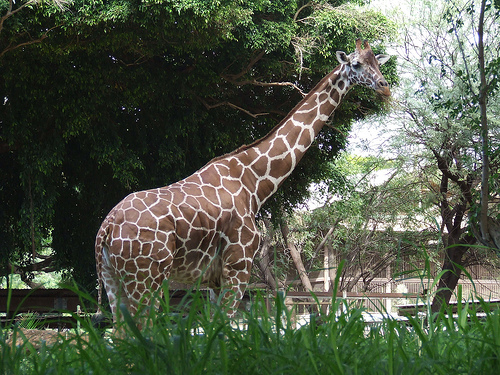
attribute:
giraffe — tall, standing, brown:
[95, 39, 390, 346]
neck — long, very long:
[214, 63, 354, 216]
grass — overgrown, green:
[1, 217, 499, 374]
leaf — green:
[266, 50, 269, 53]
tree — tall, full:
[0, 0, 400, 288]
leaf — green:
[226, 30, 227, 31]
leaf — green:
[103, 18, 106, 20]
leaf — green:
[249, 12, 251, 14]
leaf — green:
[48, 13, 49, 16]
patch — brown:
[178, 203, 196, 223]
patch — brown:
[222, 178, 242, 194]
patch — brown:
[139, 228, 155, 243]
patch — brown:
[149, 198, 170, 217]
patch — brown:
[185, 228, 208, 251]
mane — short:
[197, 63, 341, 184]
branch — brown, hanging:
[292, 1, 327, 21]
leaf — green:
[314, 1, 316, 3]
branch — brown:
[432, 55, 481, 104]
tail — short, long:
[94, 216, 110, 315]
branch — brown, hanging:
[192, 91, 269, 123]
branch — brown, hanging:
[0, 20, 64, 69]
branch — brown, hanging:
[1, 0, 31, 30]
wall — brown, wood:
[0, 288, 208, 313]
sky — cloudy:
[340, 0, 498, 158]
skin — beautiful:
[95, 39, 390, 342]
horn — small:
[356, 39, 362, 51]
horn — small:
[362, 40, 368, 49]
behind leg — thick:
[107, 221, 173, 338]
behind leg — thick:
[101, 248, 129, 338]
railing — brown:
[1, 289, 427, 299]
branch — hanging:
[219, 72, 307, 98]